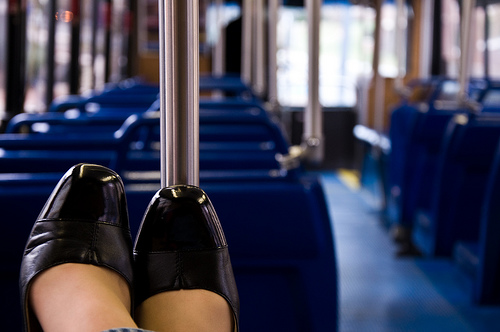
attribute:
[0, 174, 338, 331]
seat — plastic, blue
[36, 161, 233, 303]
shoes — black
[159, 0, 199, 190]
pole — stainless, silver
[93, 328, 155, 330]
jeans — blue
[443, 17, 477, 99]
pole — silver, tall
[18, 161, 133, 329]
shoes — black, reflective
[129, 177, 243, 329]
shoes — black, reflective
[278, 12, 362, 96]
lights — shining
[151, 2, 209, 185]
pole — silver, metal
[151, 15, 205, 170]
handle — silver, stainless steel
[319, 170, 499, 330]
walkway — middle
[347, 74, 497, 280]
seats — blue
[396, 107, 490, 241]
seat — blue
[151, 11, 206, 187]
pole — metal, silver, tall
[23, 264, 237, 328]
feet — woman's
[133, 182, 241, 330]
shoe — black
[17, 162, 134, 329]
shoe — black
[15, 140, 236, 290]
shoes — black